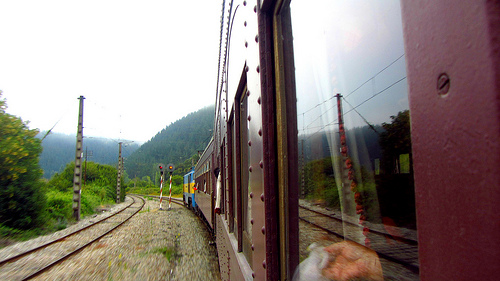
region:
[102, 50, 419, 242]
the view from a train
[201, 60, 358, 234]
the train has rivets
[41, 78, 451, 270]
there is a forest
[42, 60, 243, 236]
the tracks have gravel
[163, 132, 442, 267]
the train is red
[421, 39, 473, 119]
this is a screwhead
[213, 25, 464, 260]
the reflection in the glass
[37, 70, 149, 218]
the pine trees cover the hills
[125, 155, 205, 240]
the light poles are red and white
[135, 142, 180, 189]
red lights are on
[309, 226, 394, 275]
hand inside the train car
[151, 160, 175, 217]
two poles next to each other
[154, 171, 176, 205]
poles are red and white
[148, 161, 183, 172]
poles have red lights on them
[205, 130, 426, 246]
windows in the train car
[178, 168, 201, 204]
train car is blue with yellow stripe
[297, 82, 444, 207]
reflection of power lines in the window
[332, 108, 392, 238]
curtain in the window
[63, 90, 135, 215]
power lines next to the track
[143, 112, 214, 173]
mountain behind the train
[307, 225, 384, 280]
hand visible through the window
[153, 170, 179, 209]
two red and white striped poles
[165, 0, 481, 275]
train on the train tracks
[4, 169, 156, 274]
empty set of train tracks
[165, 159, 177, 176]
small red light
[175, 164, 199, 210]
blue and yellow train car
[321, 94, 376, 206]
reflection in the window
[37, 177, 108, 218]
bright green grass along the tracks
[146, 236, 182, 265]
small patch of grass growing in the gravel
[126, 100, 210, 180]
dark hill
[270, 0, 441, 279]
Rectangular train window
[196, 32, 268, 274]
Burgundy colored train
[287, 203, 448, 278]
Hand holding an item in a train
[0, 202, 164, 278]
Railroad tracks and gravel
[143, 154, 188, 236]
Red railroad train lights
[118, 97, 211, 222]
Hill with many green trees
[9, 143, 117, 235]
Green bushes on the side of train tracks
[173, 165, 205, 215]
Blue and yellow train car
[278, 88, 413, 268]
Reflection on a train window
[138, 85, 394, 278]
Side view of train cars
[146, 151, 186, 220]
Train track traffic signals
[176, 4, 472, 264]
Red train on train tracks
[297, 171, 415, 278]
Passenger riding on train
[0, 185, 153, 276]
Empty train tracks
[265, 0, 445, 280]
Window of red train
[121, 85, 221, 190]
Hillside along train tracks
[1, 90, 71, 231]
Citrus tree near train tracks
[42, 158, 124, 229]
Bushes along train tracks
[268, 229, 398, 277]
Train passenger's hand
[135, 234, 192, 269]
Patch of grass near train tracks